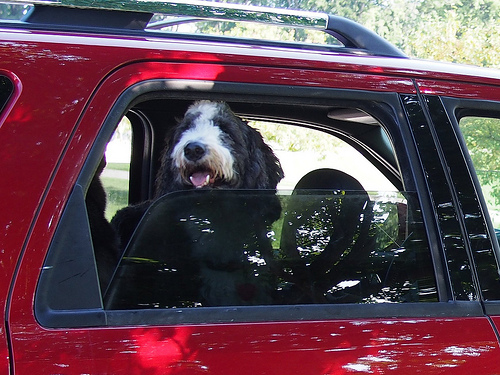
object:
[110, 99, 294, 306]
dog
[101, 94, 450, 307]
window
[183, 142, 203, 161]
nose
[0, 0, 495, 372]
car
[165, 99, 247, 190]
head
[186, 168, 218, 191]
mouth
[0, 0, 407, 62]
rack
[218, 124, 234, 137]
eyes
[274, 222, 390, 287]
reflection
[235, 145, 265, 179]
fur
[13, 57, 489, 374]
door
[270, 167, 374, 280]
headrest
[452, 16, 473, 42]
leaves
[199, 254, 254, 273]
collar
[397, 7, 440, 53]
vegetation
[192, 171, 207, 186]
tongue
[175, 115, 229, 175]
face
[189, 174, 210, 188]
teeth